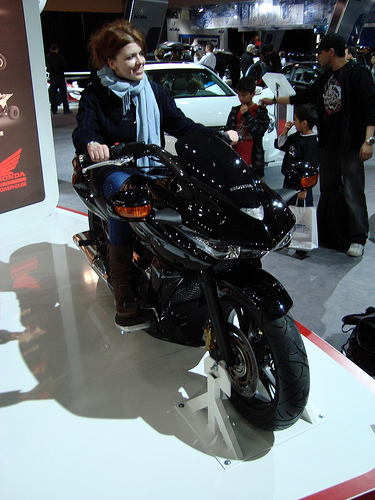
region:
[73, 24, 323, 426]
a woman on a motorcycle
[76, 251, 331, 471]
the motorcycle is clamped to the ground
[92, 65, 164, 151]
she is wearing a blue scarf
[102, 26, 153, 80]
the woman is smiling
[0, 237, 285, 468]
a shadow on the ground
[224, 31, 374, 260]
a man touching a boy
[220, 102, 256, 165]
the boy has a red shirt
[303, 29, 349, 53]
the man has a black cap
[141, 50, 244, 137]
a white car behind the woman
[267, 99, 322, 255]
a boy carrying a bag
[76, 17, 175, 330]
A woman on a motorcycle.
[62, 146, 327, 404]
A black shiny motorcycle.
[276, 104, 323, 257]
A boy in a black shirt.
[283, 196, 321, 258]
A white shopping bag.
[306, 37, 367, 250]
A man wearing next to boys.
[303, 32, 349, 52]
A black baseball cap.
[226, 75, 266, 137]
A boy touching his chin.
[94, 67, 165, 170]
A blue scarf on a woman's neck.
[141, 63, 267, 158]
A white show car.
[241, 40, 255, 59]
A man with white hair.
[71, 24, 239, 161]
Young lady sitting on a motorcycle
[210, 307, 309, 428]
Front wheel of motorcycle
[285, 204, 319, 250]
White shopping bag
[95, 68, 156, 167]
Light blue scarf worn by the young lady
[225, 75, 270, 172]
Little boy looking at the motorcycle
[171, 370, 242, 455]
White display stand for the motorcycle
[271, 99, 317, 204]
Little boy picking his nose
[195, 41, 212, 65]
Man in a white shirt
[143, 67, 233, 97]
White car in back of the young lady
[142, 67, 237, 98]
Front windshield of the white car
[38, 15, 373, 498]
people in the car and motorcycle show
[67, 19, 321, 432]
a woman on the motorcycle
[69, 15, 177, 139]
a woman wearing a blue scarf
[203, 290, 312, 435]
a front wheel of the motorcycle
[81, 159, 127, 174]
a brake control of the motorcycle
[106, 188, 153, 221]
a light of the motorcycle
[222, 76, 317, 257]
kids on the vehicle show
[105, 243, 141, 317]
boots the woman is wearing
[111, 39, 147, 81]
facial expression of the woman on the motorcycle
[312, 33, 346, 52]
a hat the person is wearing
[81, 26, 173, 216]
A lady on the motorcycle.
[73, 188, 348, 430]
The motorcycle is on display.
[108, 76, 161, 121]
The lady is wearing a blue scarf.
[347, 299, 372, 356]
Backpack on the floor.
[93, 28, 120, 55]
The lady has red hair.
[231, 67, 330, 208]
Two kids next to the man.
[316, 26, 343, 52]
The man is wearing a black cap.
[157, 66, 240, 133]
White car behind the boy.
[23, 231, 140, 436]
Motorcycle reflection on the platform.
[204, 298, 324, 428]
The wheel is black.